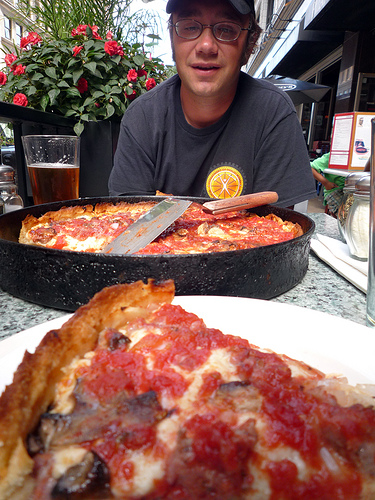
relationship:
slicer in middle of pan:
[96, 186, 280, 254] [2, 194, 314, 313]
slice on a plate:
[1, 274, 363, 496] [0, 293, 363, 398]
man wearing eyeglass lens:
[108, 0, 320, 211] [175, 20, 201, 39]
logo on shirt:
[204, 161, 248, 199] [105, 70, 317, 211]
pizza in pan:
[18, 203, 303, 254] [0, 177, 331, 303]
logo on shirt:
[205, 166, 245, 200] [105, 70, 317, 211]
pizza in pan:
[18, 203, 303, 254] [0, 194, 315, 313]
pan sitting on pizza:
[0, 194, 315, 313] [18, 203, 303, 254]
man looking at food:
[108, 0, 319, 210] [22, 199, 305, 256]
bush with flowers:
[3, 24, 165, 124] [17, 28, 39, 47]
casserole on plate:
[4, 281, 371, 497] [0, 288, 374, 391]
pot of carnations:
[0, 100, 118, 205] [2, 24, 164, 137]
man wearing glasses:
[108, 0, 319, 210] [170, 16, 249, 41]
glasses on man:
[173, 19, 249, 42] [108, 0, 319, 210]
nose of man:
[195, 31, 218, 54] [108, 0, 319, 210]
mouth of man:
[188, 61, 224, 73] [108, 0, 319, 210]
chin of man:
[186, 77, 223, 97] [108, 0, 319, 210]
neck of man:
[177, 77, 234, 124] [108, 0, 319, 210]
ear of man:
[241, 27, 256, 65] [108, 0, 319, 210]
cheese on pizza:
[52, 331, 343, 498] [0, 274, 373, 498]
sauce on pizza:
[51, 308, 372, 498] [0, 274, 373, 498]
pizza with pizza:
[18, 203, 303, 254] [18, 203, 303, 254]